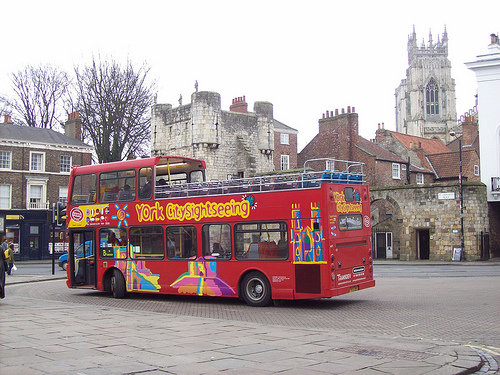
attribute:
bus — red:
[36, 133, 392, 342]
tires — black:
[107, 257, 283, 329]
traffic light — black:
[45, 199, 63, 279]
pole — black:
[41, 222, 62, 276]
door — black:
[405, 222, 439, 269]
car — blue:
[52, 246, 81, 271]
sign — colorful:
[74, 191, 255, 221]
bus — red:
[48, 140, 406, 325]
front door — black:
[1, 206, 59, 263]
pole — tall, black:
[449, 139, 477, 261]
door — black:
[409, 220, 438, 266]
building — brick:
[374, 178, 498, 262]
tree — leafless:
[65, 57, 158, 165]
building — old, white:
[146, 86, 301, 177]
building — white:
[463, 30, 497, 203]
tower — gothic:
[392, 26, 462, 151]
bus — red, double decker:
[57, 152, 384, 317]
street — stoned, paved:
[5, 243, 496, 373]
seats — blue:
[107, 171, 377, 204]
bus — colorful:
[62, 145, 381, 309]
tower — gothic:
[394, 22, 464, 144]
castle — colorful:
[286, 196, 328, 266]